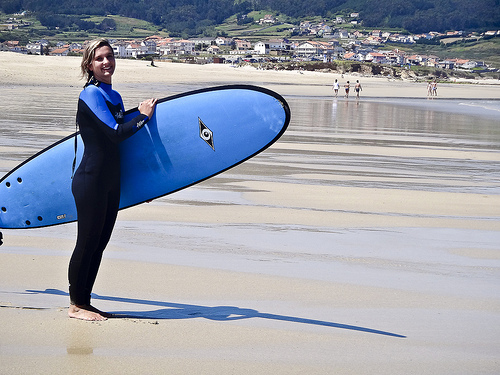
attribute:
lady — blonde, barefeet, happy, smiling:
[60, 32, 164, 326]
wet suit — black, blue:
[60, 83, 143, 316]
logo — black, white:
[186, 114, 225, 162]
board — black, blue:
[2, 87, 295, 234]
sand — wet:
[329, 193, 456, 247]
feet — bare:
[57, 297, 118, 326]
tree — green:
[36, 11, 95, 31]